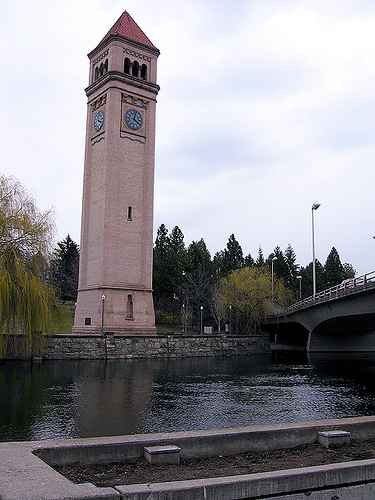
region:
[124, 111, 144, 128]
it is a clock on the tower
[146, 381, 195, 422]
it is a stream of water below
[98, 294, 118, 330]
it is a lamp post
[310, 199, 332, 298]
it is a street light up above near the road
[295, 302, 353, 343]
it is a bridge to the side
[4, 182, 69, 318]
a green tree in the foreground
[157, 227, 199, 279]
green trees in the background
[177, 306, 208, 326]
more lampposts in the background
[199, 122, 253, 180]
a cloudy sky is up above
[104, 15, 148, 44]
it is the red roof of the tower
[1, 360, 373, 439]
the murky water under the bridge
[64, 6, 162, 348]
the tall clock tower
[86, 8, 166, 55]
the roof of the clock tower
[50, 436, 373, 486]
the dirt in the foreground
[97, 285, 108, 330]
light post in front of the clock tower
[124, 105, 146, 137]
clock on the front of the clock tower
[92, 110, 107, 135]
clock on the side of the clock tower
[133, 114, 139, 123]
clock hands on front clock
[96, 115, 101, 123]
clock hands on side clock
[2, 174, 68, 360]
partial tree hanging over the water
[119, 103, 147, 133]
A clock on a tower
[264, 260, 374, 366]
A bridge over a river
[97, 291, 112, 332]
A black lampost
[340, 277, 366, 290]
A red car crossing bridge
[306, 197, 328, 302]
White lamppost on bridge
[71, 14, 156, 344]
A clock tower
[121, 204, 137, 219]
A window on the tower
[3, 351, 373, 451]
River under bridge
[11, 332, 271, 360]
A grey stone wall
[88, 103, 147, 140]
Two clocks on the tower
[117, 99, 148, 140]
a clock on a stone tower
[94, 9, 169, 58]
red clay roof of a tower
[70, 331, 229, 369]
stone wall by the water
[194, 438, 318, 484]
dirt by a cement wall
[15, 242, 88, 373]
weeping willow over the water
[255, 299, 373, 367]
a bridge over the water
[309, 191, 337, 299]
street light on a pole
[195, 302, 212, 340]
street lamp in a park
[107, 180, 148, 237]
window in a stone tower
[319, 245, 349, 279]
evergreen tree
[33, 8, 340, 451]
tower on the bank of a river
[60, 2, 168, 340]
four-sided tower with a pointed roof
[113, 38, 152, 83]
three arches below a row of stone decorations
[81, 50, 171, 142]
border separating arches from clock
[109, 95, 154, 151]
clock showing it is early afternoon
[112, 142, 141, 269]
short narrow opening on body of tower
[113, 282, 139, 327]
opening resembling lipstick in case at tower base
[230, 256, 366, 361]
car crossing river on bridge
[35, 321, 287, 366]
stone wall facing the river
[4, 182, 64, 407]
willow tree hanging over river